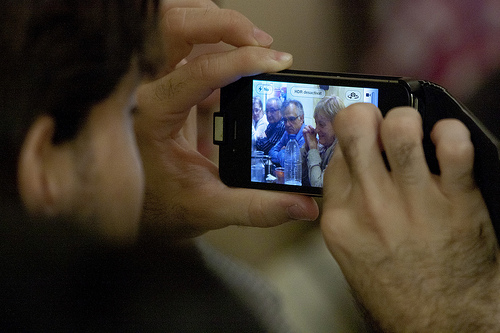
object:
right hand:
[317, 103, 500, 332]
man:
[269, 101, 309, 174]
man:
[258, 98, 283, 150]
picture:
[252, 77, 380, 189]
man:
[0, 0, 499, 331]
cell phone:
[210, 70, 499, 197]